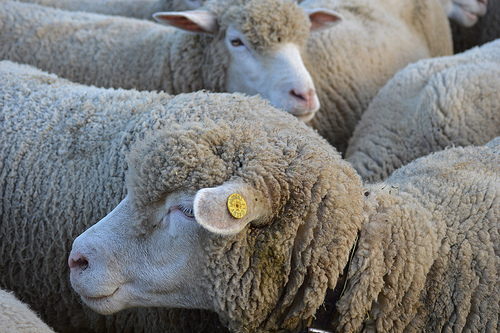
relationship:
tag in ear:
[228, 195, 249, 219] [193, 180, 256, 238]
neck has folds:
[306, 141, 375, 331] [295, 174, 367, 332]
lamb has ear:
[69, 91, 498, 330] [193, 180, 256, 238]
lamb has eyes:
[69, 91, 498, 330] [175, 205, 195, 218]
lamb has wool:
[69, 91, 498, 330] [0, 62, 204, 326]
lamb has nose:
[69, 91, 498, 330] [69, 250, 90, 272]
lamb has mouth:
[69, 91, 498, 330] [77, 284, 121, 302]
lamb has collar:
[69, 91, 498, 330] [317, 227, 364, 323]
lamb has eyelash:
[69, 91, 498, 330] [178, 205, 191, 214]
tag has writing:
[228, 195, 249, 219] [230, 196, 245, 217]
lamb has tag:
[69, 91, 498, 330] [228, 195, 249, 219]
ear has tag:
[193, 180, 256, 238] [228, 195, 249, 219]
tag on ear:
[228, 195, 249, 219] [193, 180, 256, 238]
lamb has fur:
[69, 91, 498, 330] [128, 119, 496, 332]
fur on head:
[128, 119, 496, 332] [125, 100, 361, 209]